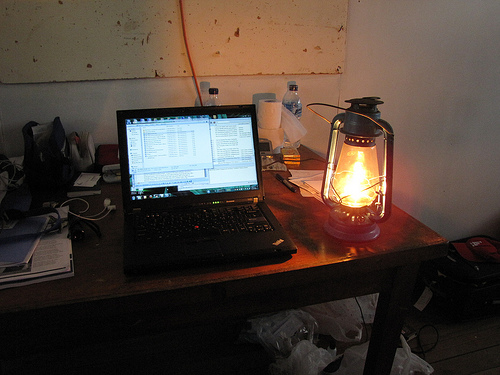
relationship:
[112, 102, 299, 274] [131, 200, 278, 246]
laptop with keyboard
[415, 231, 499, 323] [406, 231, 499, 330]
luggage for belongings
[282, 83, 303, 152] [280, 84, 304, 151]
water for consumption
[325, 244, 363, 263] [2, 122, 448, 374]
brown wooden desk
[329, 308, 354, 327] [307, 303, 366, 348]
white plastic bag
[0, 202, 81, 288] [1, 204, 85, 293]
book for learning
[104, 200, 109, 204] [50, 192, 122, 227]
white electronic cord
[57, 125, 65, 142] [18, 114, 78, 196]
blue lunch box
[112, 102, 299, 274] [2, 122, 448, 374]
laptop on desk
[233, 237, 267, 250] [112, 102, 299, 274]
black powered laptop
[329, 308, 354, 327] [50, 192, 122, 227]
white usb cord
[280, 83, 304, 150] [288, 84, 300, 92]
bottle with top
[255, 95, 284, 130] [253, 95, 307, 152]
roll of paper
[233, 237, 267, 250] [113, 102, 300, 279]
black writing instrument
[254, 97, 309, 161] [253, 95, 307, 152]
rolls of paper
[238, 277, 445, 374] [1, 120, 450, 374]
bags under table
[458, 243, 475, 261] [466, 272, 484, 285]
red and black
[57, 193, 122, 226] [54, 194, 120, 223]
pair of earbuds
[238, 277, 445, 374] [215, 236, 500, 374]
bags on floor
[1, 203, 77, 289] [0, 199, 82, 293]
stack of paper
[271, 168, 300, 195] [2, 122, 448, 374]
pen on desk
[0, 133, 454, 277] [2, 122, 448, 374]
wooden large desk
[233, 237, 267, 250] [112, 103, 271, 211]
black lap top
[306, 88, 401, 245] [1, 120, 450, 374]
latern on table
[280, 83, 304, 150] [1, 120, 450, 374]
bottle on table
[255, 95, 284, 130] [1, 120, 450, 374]
roll on table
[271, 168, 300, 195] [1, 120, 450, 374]
pen on table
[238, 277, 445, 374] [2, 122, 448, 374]
bags under desk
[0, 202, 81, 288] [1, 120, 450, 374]
books on table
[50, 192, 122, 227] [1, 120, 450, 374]
cord on table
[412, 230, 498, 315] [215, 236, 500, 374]
bag on floor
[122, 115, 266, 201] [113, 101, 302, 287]
screen on computer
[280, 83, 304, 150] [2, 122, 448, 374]
bottle on desk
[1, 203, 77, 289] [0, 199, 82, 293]
stack of papers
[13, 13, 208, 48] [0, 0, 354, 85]
white chipped board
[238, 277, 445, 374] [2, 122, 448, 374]
bags underneath desk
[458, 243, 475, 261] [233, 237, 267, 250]
red and black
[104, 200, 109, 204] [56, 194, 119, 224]
white charger cable